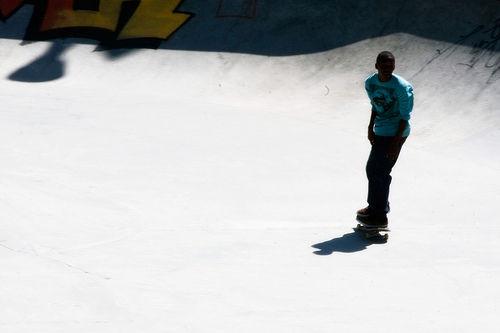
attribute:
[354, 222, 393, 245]
skate — black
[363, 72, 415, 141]
shirt — blue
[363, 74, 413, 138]
shirt — wrinkles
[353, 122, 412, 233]
pants — dark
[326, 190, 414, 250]
skateboard. — rolling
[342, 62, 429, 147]
shirt — blue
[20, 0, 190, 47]
graffiti — yellow and black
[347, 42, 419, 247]
skateboarder — skating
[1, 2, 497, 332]
park — gray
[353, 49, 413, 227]
boy — skating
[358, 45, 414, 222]
boy — rolling